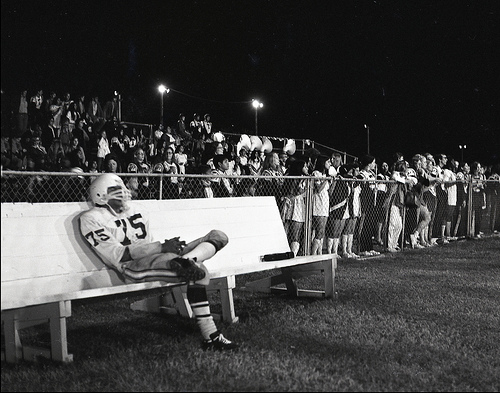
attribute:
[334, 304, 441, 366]
grass lawn — maintained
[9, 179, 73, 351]
bench — wooden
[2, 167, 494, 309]
fence — chain link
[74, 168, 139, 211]
helmet — white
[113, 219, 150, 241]
number — 75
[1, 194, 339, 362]
bench — long, white, wooden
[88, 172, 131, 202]
helmet — white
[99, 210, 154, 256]
number — large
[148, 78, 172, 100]
light — bright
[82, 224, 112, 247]
number75 — small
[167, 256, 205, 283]
shoe — spiked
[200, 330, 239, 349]
shoe — spiked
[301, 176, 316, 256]
post — metal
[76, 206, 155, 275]
jersey — white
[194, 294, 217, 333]
sock — long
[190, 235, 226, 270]
sock — long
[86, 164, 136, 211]
helmet — white